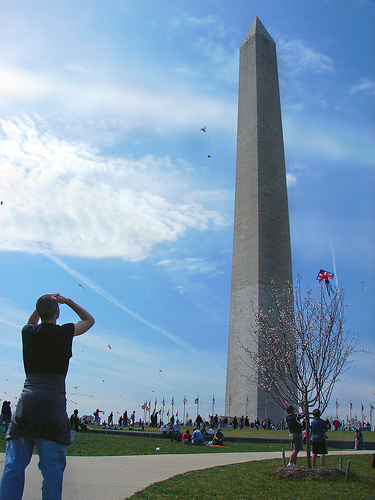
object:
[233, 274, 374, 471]
tree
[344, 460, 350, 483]
pole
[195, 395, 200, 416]
flag pole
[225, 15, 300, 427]
monument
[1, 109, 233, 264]
clouds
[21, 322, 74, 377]
shirt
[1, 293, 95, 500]
man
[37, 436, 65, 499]
leg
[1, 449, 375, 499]
walkway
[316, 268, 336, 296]
kite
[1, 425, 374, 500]
grass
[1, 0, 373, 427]
sky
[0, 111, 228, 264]
cloud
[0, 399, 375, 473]
crowd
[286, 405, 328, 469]
people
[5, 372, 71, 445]
sweatshirt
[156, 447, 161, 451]
object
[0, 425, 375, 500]
ground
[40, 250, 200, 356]
streak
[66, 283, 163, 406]
kites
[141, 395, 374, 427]
flags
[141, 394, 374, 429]
poles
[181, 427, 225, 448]
people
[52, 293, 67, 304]
hands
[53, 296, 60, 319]
face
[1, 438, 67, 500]
jeans